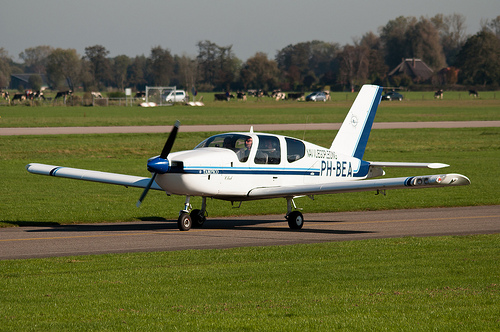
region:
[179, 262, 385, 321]
a field of grass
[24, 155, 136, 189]
the wing of the plane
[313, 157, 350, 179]
writing on the plane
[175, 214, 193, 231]
the front wheel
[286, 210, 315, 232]
back wheel of the plane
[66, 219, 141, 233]
a shadow on the roadway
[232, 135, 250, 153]
the driver of the plane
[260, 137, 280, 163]
a window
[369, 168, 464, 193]
the left wing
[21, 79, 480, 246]
white airplane with blue stripes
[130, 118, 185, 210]
blue airplane prop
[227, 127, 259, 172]
man inside small aircraft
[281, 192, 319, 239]
landing gear with black tire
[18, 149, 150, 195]
white airplane wing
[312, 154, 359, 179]
black letters on the side of white plane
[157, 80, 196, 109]
gray van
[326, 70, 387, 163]
white tail with blue stripe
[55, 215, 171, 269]
gray asphalt with yellow stripe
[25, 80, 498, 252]
Plane on a runway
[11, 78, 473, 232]
Plane is on a runway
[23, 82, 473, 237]
Airplane on a runway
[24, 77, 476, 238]
Airplane is on a runway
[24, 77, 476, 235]
Blue and white plane on a runway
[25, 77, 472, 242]
Blue and white plane is on a runway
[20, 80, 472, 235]
Blue and white airplane on a runway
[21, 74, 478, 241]
Blue and white airplane is on a runway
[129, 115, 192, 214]
Propellor is on front of plane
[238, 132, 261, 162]
Man is inside a plane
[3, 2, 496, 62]
blue of daytime sky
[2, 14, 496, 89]
line of trees on horizon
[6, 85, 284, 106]
farm animals in the distance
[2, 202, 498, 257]
paved surface of runway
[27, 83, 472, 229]
plane on top of runway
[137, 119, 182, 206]
propeller on front of plane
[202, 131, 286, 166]
pilot in plane cockpit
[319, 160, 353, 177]
letters on side of plane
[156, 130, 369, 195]
white plane with blue stripes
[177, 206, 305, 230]
wheels of landing gear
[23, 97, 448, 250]
airplane on the ground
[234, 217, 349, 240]
shadow of the wing on the ground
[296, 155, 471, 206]
wing of the airplane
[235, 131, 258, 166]
pilot inside the plane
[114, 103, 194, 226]
propeller on the front of the plane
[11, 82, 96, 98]
cows in a field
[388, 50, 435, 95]
house behind the field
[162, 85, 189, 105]
car across the field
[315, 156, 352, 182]
letters on the plane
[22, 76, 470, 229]
a small white airplane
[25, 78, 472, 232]
a white and blue plane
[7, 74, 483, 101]
a field of cows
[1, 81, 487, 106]
cows eating grass in a field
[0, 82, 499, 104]
cows grazing in a farm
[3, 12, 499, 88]
trees surrounding a farm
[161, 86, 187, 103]
a small gray mini van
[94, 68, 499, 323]
this is a plane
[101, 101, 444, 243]
the plane is white and blue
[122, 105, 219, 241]
this is a propeller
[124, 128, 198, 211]
the propeller is blue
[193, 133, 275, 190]
the plane is striped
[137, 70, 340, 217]
this is a cockpit